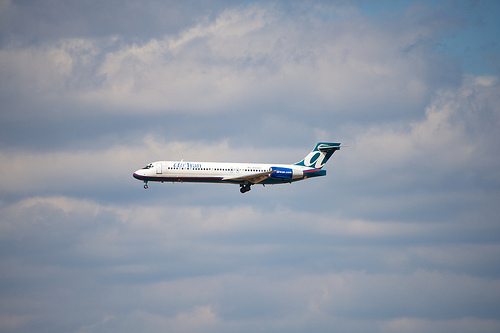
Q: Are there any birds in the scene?
A: Yes, there is a bird.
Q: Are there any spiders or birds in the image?
A: Yes, there is a bird.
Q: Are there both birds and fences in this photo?
A: No, there is a bird but no fences.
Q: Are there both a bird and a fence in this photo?
A: No, there is a bird but no fences.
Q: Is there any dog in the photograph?
A: No, there are no dogs.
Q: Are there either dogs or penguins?
A: No, there are no dogs or penguins.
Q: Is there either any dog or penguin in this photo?
A: No, there are no dogs or penguins.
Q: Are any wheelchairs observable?
A: No, there are no wheelchairs.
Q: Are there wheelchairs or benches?
A: No, there are no wheelchairs or benches.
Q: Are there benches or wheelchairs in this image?
A: No, there are no wheelchairs or benches.